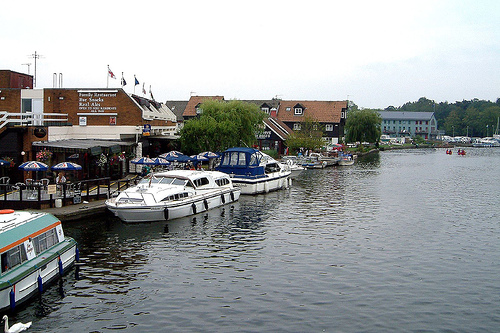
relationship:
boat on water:
[106, 174, 233, 220] [279, 255, 345, 304]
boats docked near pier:
[110, 145, 290, 220] [67, 207, 87, 218]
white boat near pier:
[177, 210, 188, 215] [67, 207, 87, 218]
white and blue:
[177, 210, 188, 215] [246, 166, 255, 172]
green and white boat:
[15, 229, 27, 235] [106, 174, 233, 220]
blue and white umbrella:
[246, 166, 255, 172] [54, 160, 80, 172]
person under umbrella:
[57, 172, 67, 182] [54, 160, 80, 172]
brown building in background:
[125, 102, 133, 114] [273, 104, 347, 137]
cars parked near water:
[449, 134, 472, 144] [279, 255, 345, 304]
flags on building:
[106, 66, 147, 90] [53, 95, 151, 126]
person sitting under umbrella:
[57, 172, 67, 182] [54, 160, 80, 172]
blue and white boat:
[246, 166, 255, 172] [106, 174, 233, 220]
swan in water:
[1, 315, 36, 333] [279, 255, 345, 304]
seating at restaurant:
[22, 179, 44, 198] [79, 91, 119, 119]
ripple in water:
[350, 180, 378, 204] [279, 255, 345, 304]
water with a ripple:
[279, 255, 345, 304] [350, 180, 378, 204]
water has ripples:
[279, 255, 345, 304] [177, 255, 242, 293]